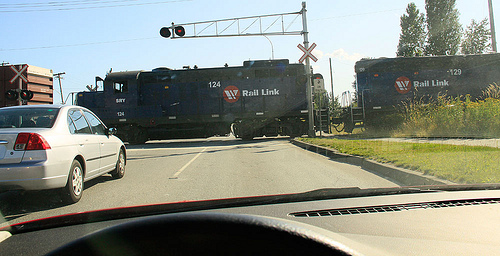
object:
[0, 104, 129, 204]
car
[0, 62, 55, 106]
box car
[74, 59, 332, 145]
engine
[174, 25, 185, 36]
light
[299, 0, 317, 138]
post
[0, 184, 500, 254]
dashboard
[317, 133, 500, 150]
sidewalk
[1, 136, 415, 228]
street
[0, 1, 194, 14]
powerline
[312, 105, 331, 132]
stair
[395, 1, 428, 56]
tree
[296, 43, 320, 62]
sign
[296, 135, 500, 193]
grass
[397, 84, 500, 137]
weeds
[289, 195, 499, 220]
vent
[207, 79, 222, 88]
number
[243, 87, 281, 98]
lettering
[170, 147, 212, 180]
line